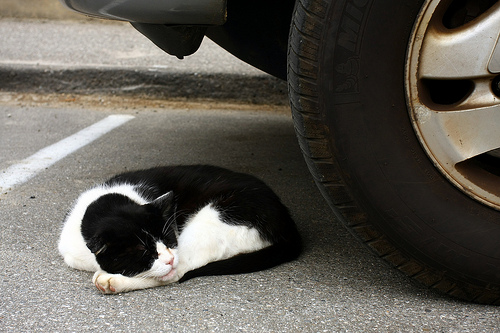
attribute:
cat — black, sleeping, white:
[57, 164, 305, 295]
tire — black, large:
[286, 0, 500, 307]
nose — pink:
[167, 256, 174, 266]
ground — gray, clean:
[0, 18, 500, 331]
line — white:
[0, 113, 137, 197]